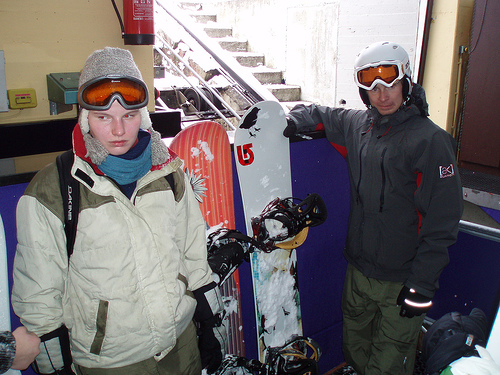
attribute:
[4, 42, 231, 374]
snowboarder — dressed, snowy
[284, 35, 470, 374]
snowboarder — dressed, snowy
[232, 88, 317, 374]
snowboard — white, unique, color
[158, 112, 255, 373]
snowboard — orange, unique, color, pink, red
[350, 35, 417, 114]
helmet — white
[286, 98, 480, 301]
jacket — gray, dark gray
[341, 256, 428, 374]
pants — green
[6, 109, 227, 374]
coat — tan, puffy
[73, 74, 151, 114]
googles — goggles, orange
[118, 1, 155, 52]
extinguisher — red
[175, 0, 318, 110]
stairs — lit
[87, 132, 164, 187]
scarf — blue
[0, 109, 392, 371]
wall — blue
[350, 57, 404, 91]
goggles — orange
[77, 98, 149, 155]
face — white